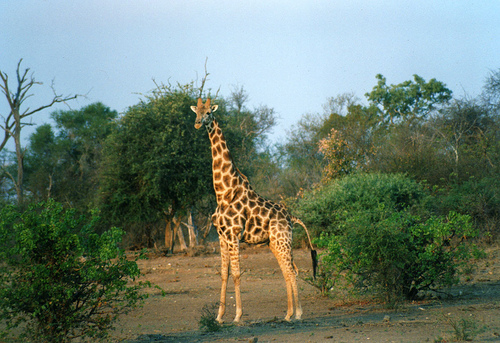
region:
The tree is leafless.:
[0, 55, 85, 202]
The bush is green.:
[303, 197, 498, 324]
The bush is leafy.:
[1, 192, 175, 342]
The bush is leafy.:
[297, 201, 493, 321]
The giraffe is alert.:
[176, 81, 327, 341]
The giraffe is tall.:
[182, 88, 332, 334]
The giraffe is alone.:
[177, 88, 333, 332]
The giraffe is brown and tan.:
[186, 79, 326, 335]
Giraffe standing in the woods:
[188, 95, 321, 326]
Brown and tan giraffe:
[185, 93, 322, 324]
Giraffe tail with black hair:
[291, 218, 318, 278]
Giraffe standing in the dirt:
[185, 94, 322, 325]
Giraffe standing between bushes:
[187, 94, 322, 324]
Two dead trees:
[0, 56, 77, 198]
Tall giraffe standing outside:
[186, 96, 320, 325]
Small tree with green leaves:
[0, 195, 164, 342]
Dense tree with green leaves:
[87, 86, 252, 251]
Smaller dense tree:
[277, 168, 485, 313]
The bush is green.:
[305, 205, 480, 332]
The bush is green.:
[295, 160, 421, 303]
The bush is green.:
[2, 191, 167, 341]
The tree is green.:
[88, 59, 250, 265]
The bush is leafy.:
[303, 198, 483, 319]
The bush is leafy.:
[279, 172, 431, 311]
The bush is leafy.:
[0, 193, 169, 341]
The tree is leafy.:
[93, 60, 264, 268]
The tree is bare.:
[1, 56, 83, 206]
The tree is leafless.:
[1, 56, 88, 216]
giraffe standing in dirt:
[181, 90, 329, 325]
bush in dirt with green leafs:
[286, 165, 487, 314]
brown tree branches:
[0, 51, 82, 201]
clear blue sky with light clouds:
[289, 26, 331, 59]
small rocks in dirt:
[151, 259, 181, 274]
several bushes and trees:
[393, 103, 483, 184]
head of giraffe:
[182, 95, 228, 131]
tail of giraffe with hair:
[291, 208, 329, 279]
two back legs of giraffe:
[270, 231, 315, 327]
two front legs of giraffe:
[203, 233, 261, 335]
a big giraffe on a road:
[183, 88, 326, 331]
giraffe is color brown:
[181, 86, 330, 327]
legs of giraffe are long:
[213, 241, 309, 331]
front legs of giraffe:
[211, 241, 249, 328]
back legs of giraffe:
[268, 243, 308, 325]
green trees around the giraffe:
[6, 43, 498, 340]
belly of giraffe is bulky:
[239, 219, 270, 251]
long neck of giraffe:
[204, 116, 249, 197]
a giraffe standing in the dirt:
[185, 99, 319, 324]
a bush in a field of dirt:
[285, 173, 468, 318]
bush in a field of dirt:
[0, 199, 170, 341]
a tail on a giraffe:
[290, 218, 320, 279]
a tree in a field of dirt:
[110, 94, 232, 259]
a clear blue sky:
[0, 0, 497, 156]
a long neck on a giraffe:
[205, 122, 240, 193]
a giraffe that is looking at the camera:
[188, 92, 322, 324]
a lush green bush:
[1, 185, 156, 341]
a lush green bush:
[286, 166, 496, 311]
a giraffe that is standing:
[178, 90, 320, 326]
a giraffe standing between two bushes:
[4, 167, 498, 340]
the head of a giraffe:
[187, 94, 221, 133]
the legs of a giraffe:
[212, 214, 306, 331]